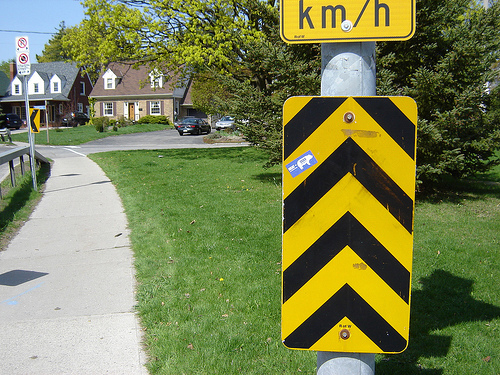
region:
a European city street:
[13, 4, 466, 374]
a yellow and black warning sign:
[264, 80, 429, 355]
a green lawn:
[123, 158, 234, 315]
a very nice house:
[90, 50, 206, 135]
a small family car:
[170, 111, 213, 141]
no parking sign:
[11, 22, 42, 102]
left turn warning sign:
[23, 98, 49, 138]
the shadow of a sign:
[420, 256, 485, 361]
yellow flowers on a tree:
[56, 5, 271, 100]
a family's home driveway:
[93, 120, 215, 152]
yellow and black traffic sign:
[277, 2, 420, 373]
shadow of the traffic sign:
[414, 266, 498, 373]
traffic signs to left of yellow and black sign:
[15, 34, 30, 80]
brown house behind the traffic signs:
[87, 55, 214, 127]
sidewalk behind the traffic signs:
[50, 157, 102, 204]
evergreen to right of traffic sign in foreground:
[420, 0, 498, 185]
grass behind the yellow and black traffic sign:
[218, 264, 279, 304]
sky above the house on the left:
[0, 1, 60, 37]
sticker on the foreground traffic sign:
[284, 149, 319, 177]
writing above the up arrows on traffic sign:
[292, 1, 396, 30]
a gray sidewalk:
[0, 150, 155, 373]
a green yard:
[87, 142, 497, 372]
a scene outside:
[7, 2, 477, 373]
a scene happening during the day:
[5, 5, 498, 367]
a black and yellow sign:
[271, 86, 421, 356]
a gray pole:
[295, 0, 400, 374]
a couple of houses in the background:
[0, 43, 239, 135]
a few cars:
[0, 96, 268, 144]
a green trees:
[184, 8, 498, 194]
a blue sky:
[0, 1, 104, 61]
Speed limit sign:
[272, 0, 428, 45]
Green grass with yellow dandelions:
[144, 160, 271, 305]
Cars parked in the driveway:
[172, 113, 249, 141]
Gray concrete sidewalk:
[0, 159, 145, 364]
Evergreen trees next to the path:
[413, 6, 498, 212]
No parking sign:
[12, 35, 34, 52]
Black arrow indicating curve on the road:
[28, 101, 51, 146]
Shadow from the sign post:
[411, 251, 498, 373]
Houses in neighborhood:
[5, 61, 215, 138]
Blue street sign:
[32, 100, 47, 113]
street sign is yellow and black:
[282, 86, 465, 357]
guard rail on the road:
[0, 143, 37, 196]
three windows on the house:
[3, 70, 73, 99]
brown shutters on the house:
[97, 101, 188, 121]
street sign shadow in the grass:
[356, 252, 495, 368]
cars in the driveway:
[162, 107, 245, 141]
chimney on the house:
[2, 59, 29, 100]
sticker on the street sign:
[288, 150, 329, 187]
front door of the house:
[118, 100, 151, 131]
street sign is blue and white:
[30, 102, 48, 115]